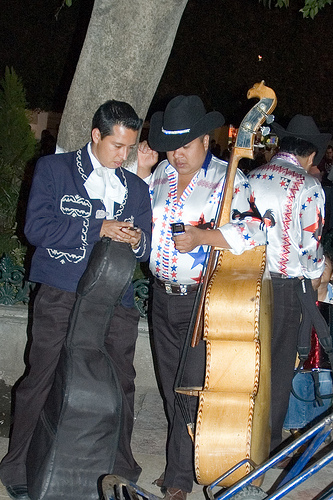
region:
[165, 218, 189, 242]
the man is looking at his phone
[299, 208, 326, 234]
the star is red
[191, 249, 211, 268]
the star is blue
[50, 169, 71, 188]
the shirt is blue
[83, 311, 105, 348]
the case is black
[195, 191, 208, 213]
the shirt is white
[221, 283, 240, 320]
the instrument is brown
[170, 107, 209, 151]
the hat is on his head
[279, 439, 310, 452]
the pipe has lost its paint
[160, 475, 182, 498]
the boot is brown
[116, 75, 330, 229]
Black cowboy hat on the man.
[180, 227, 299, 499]
Violin case by the man.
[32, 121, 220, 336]
Man wearing a bolero.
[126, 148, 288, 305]
Stars on the shirt.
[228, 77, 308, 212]
Handle of the cello.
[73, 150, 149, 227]
White tie on the man.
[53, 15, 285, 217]
Tree trunk in the background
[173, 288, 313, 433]
Strings on the cello.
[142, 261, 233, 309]
Belt on the man,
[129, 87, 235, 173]
Hat with ribbon.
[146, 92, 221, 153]
a man's black hat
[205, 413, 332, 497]
part of a blue pole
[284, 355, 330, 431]
part of a blue bag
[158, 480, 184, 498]
part of a man's brown shoe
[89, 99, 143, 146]
a man's short black hair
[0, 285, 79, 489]
the leg of a man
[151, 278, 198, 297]
part of a man's belt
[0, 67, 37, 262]
a tall green tree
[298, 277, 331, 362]
a long black strap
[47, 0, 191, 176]
a large tree branch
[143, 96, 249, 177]
the hat is black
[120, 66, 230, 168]
the hat is black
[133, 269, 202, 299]
man wearing a belt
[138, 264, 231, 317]
man wearing a belt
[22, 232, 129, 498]
Man holding a cello case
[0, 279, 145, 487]
Man is wearing pants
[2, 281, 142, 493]
Man is wearing black pants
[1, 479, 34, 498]
Man is wearing shoes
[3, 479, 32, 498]
Man is wearing black shoes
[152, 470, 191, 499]
Man is wearing brown shoes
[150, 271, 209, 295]
Man is wearing a belt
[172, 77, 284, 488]
Man is holding a cello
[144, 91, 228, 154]
Man is wearing a hat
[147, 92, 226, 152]
Man is wearing a black hat